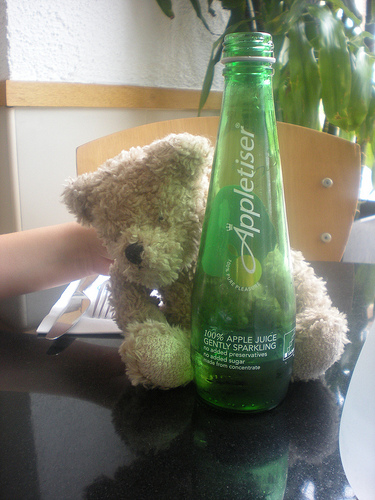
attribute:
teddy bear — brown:
[57, 128, 350, 393]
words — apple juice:
[204, 329, 279, 352]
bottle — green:
[183, 33, 314, 364]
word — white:
[226, 121, 254, 270]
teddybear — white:
[39, 131, 347, 394]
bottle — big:
[178, 28, 298, 409]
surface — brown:
[37, 345, 357, 481]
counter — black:
[0, 259, 372, 499]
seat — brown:
[68, 113, 363, 266]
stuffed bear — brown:
[59, 130, 351, 387]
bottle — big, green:
[184, 24, 303, 417]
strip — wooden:
[0, 79, 222, 110]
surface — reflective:
[9, 327, 365, 489]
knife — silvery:
[43, 268, 118, 354]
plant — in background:
[159, 2, 373, 165]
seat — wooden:
[292, 123, 365, 260]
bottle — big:
[208, 43, 304, 337]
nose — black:
[119, 238, 146, 263]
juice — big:
[205, 29, 302, 421]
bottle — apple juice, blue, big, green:
[189, 32, 297, 411]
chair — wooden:
[74, 113, 362, 263]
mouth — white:
[112, 235, 170, 287]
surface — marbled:
[2, 256, 373, 498]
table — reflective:
[72, 356, 118, 390]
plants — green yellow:
[160, 0, 374, 140]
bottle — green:
[183, 20, 359, 393]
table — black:
[102, 416, 336, 488]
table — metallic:
[40, 363, 305, 493]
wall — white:
[1, 2, 224, 86]